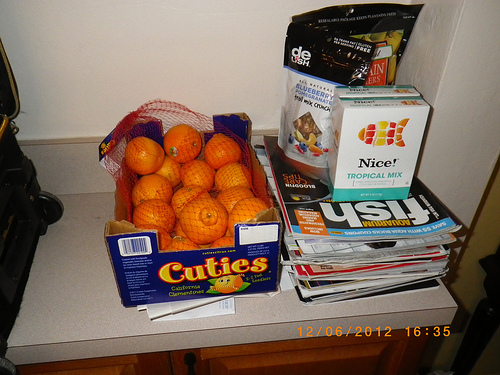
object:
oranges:
[120, 118, 271, 255]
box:
[325, 96, 433, 203]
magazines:
[251, 127, 464, 307]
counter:
[0, 192, 463, 374]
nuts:
[274, 21, 379, 183]